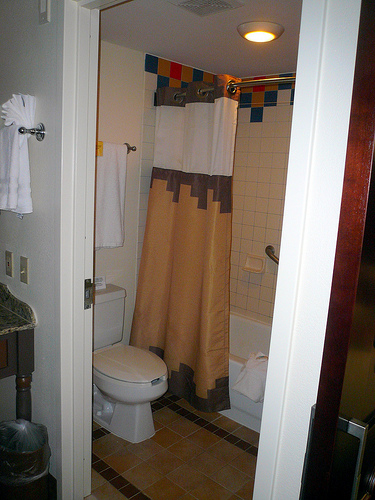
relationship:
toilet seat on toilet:
[92, 342, 168, 388] [92, 279, 169, 444]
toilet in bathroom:
[86, 272, 173, 417] [14, 16, 264, 493]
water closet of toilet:
[90, 279, 132, 350] [92, 279, 169, 444]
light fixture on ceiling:
[220, 19, 277, 51] [109, 8, 227, 73]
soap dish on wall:
[239, 251, 266, 272] [229, 70, 295, 326]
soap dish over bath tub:
[239, 251, 266, 272] [217, 299, 289, 417]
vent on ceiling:
[172, 2, 241, 17] [99, 1, 301, 79]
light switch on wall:
[17, 256, 28, 283] [0, 1, 65, 488]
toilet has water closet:
[86, 277, 171, 444] [88, 279, 126, 351]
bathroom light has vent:
[222, 7, 290, 50] [172, 2, 241, 17]